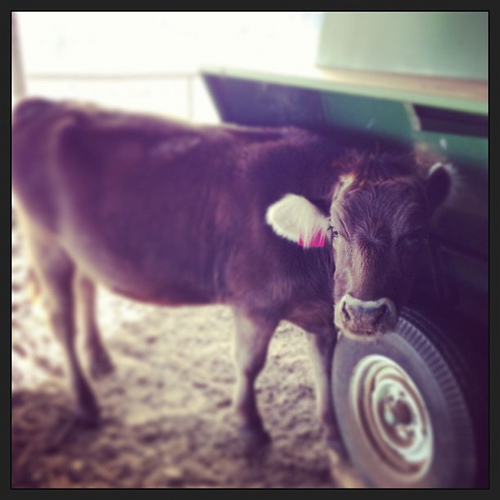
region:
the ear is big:
[262, 204, 396, 281]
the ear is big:
[263, 187, 353, 304]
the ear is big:
[249, 155, 363, 275]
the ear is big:
[259, 187, 331, 261]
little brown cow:
[0, 91, 467, 466]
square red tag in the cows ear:
[287, 204, 332, 256]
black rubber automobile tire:
[298, 281, 495, 485]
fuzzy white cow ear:
[250, 180, 335, 254]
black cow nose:
[322, 286, 413, 348]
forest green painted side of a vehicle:
[180, 59, 499, 309]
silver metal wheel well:
[333, 345, 441, 487]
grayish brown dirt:
[11, 279, 341, 487]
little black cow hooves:
[224, 410, 355, 459]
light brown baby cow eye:
[327, 219, 342, 244]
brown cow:
[30, 101, 448, 386]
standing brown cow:
[16, 106, 448, 390]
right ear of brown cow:
[266, 190, 330, 260]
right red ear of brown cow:
[265, 187, 330, 253]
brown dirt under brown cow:
[122, 315, 213, 463]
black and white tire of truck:
[326, 340, 481, 482]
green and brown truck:
[213, 15, 478, 120]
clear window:
[26, 19, 295, 62]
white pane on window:
[19, 20, 175, 91]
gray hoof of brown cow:
[233, 420, 271, 448]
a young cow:
[5, 63, 481, 480]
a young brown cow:
[24, 71, 465, 468]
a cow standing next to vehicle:
[41, 9, 499, 464]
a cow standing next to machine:
[16, 68, 494, 470]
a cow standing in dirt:
[19, 49, 429, 489]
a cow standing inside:
[14, 54, 442, 493]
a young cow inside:
[19, 80, 498, 424]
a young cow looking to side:
[34, 79, 457, 453]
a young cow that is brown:
[16, 35, 448, 499]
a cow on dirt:
[29, 79, 482, 464]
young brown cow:
[20, 51, 461, 441]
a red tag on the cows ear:
[271, 195, 357, 273]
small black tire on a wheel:
[319, 290, 473, 491]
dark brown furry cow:
[54, 73, 454, 358]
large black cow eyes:
[323, 209, 452, 261]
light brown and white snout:
[317, 285, 414, 349]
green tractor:
[194, 21, 486, 331]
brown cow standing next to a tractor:
[16, 50, 495, 482]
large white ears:
[259, 119, 459, 274]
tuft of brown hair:
[323, 126, 414, 211]